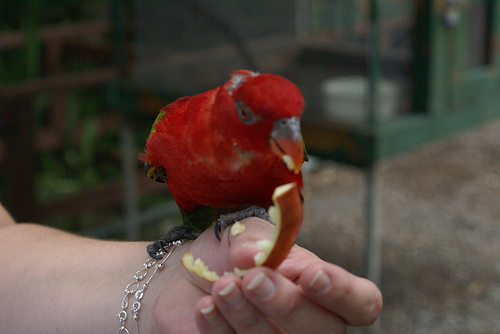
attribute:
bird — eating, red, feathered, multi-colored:
[140, 69, 305, 254]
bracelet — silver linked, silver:
[115, 240, 182, 327]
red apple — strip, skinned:
[181, 182, 303, 295]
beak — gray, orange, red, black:
[268, 118, 305, 173]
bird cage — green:
[117, 0, 497, 313]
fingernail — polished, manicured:
[246, 272, 274, 300]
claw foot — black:
[144, 211, 201, 261]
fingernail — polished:
[218, 282, 241, 309]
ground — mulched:
[102, 118, 500, 332]